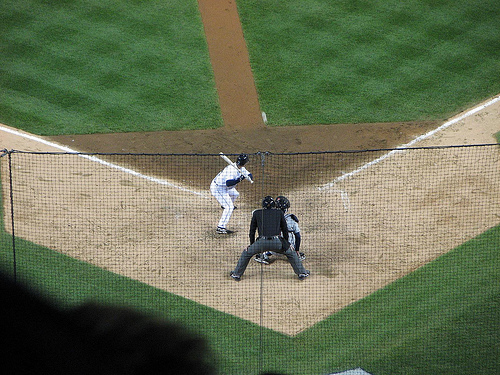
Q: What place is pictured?
A: It is a field.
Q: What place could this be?
A: It is a field.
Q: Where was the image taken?
A: It was taken at the field.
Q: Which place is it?
A: It is a field.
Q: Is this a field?
A: Yes, it is a field.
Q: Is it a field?
A: Yes, it is a field.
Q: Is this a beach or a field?
A: It is a field.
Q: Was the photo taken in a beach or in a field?
A: It was taken at a field.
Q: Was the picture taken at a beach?
A: No, the picture was taken in a field.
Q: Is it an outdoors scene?
A: Yes, it is outdoors.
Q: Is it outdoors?
A: Yes, it is outdoors.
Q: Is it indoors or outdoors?
A: It is outdoors.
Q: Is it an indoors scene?
A: No, it is outdoors.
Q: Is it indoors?
A: No, it is outdoors.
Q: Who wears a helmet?
A: The player wears a helmet.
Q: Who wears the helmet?
A: The player wears a helmet.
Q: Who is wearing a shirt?
A: The player is wearing a shirt.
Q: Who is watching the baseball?
A: The player is watching the baseball.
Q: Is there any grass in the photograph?
A: Yes, there is grass.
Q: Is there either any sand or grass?
A: Yes, there is grass.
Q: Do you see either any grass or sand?
A: Yes, there is grass.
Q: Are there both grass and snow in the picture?
A: No, there is grass but no snow.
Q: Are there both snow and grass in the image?
A: No, there is grass but no snow.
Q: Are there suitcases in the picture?
A: No, there are no suitcases.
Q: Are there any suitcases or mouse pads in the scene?
A: No, there are no suitcases or mouse pads.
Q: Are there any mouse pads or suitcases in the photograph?
A: No, there are no suitcases or mouse pads.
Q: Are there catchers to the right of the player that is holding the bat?
A: Yes, there is a catcher to the right of the player.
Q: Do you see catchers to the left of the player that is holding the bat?
A: No, the catcher is to the right of the player.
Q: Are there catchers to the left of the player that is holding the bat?
A: No, the catcher is to the right of the player.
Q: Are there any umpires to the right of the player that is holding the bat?
A: No, there is a catcher to the right of the player.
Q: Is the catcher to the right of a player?
A: Yes, the catcher is to the right of a player.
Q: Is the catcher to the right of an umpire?
A: No, the catcher is to the right of a player.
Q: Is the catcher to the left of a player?
A: No, the catcher is to the right of a player.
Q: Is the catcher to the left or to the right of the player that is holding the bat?
A: The catcher is to the right of the player.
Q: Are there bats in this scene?
A: Yes, there is a bat.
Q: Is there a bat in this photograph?
A: Yes, there is a bat.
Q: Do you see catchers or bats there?
A: Yes, there is a bat.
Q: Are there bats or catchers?
A: Yes, there is a bat.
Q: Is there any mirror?
A: No, there are no mirrors.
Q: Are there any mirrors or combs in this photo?
A: No, there are no mirrors or combs.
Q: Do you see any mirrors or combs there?
A: No, there are no mirrors or combs.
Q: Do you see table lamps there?
A: No, there are no table lamps.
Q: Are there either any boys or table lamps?
A: No, there are no table lamps or boys.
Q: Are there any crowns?
A: No, there are no crowns.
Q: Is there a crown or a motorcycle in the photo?
A: No, there are no crowns or motorcycles.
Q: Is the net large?
A: Yes, the net is large.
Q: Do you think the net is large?
A: Yes, the net is large.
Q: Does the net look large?
A: Yes, the net is large.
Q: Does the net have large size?
A: Yes, the net is large.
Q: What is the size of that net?
A: The net is large.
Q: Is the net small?
A: No, the net is large.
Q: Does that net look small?
A: No, the net is large.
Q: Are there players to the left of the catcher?
A: Yes, there is a player to the left of the catcher.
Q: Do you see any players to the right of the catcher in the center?
A: No, the player is to the left of the catcher.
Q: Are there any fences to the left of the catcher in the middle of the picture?
A: No, there is a player to the left of the catcher.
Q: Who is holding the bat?
A: The player is holding the bat.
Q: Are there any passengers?
A: No, there are no passengers.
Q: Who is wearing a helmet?
A: The player is wearing a helmet.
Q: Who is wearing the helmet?
A: The player is wearing a helmet.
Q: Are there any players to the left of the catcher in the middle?
A: Yes, there is a player to the left of the catcher.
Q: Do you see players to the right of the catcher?
A: No, the player is to the left of the catcher.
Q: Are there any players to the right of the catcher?
A: No, the player is to the left of the catcher.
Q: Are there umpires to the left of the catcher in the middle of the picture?
A: No, there is a player to the left of the catcher.